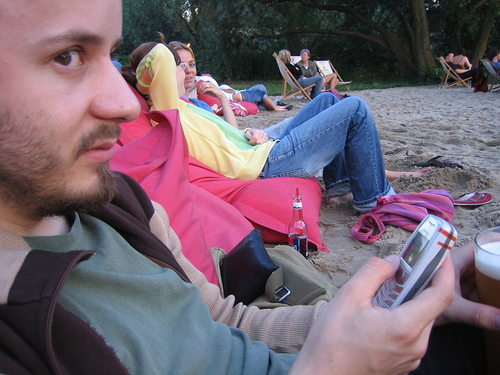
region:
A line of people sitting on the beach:
[8, 0, 281, 373]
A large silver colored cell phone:
[357, 213, 464, 315]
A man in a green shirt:
[6, 2, 288, 374]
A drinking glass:
[471, 217, 499, 309]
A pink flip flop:
[436, 183, 498, 212]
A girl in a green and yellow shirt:
[136, 39, 268, 171]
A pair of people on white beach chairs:
[267, 46, 332, 106]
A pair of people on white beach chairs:
[432, 42, 472, 91]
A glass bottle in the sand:
[277, 185, 327, 255]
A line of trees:
[124, 2, 499, 78]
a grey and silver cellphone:
[368, 210, 460, 312]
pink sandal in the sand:
[453, 189, 495, 209]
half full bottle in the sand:
[286, 187, 309, 258]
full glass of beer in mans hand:
[473, 223, 499, 364]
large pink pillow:
[118, 82, 324, 248]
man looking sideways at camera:
[1, 0, 144, 212]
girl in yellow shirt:
[131, 38, 279, 176]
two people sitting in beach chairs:
[268, 45, 354, 104]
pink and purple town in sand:
[351, 187, 454, 245]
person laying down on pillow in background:
[219, 84, 291, 114]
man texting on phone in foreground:
[10, 7, 493, 357]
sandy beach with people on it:
[305, 74, 497, 212]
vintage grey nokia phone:
[350, 203, 451, 321]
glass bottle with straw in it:
[263, 177, 330, 255]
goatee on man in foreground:
[65, 125, 135, 218]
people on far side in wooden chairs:
[265, 59, 347, 105]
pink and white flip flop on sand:
[444, 183, 498, 203]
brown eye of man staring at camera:
[45, 38, 83, 73]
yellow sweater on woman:
[145, 48, 289, 192]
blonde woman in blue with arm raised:
[168, 42, 241, 120]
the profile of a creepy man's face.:
[0, 0, 141, 232]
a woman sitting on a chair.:
[133, 20, 469, 265]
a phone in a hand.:
[353, 206, 477, 334]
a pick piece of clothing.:
[118, 105, 342, 283]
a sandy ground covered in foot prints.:
[262, 89, 497, 292]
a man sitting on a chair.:
[266, 46, 353, 118]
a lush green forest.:
[95, 1, 496, 84]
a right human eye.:
[31, 34, 109, 81]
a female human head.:
[122, 36, 194, 126]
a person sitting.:
[155, 39, 205, 104]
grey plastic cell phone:
[365, 206, 457, 316]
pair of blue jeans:
[262, 90, 392, 202]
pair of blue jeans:
[293, 73, 328, 98]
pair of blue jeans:
[237, 81, 275, 106]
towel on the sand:
[345, 181, 454, 251]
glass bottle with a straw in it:
[281, 183, 310, 261]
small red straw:
[291, 181, 297, 202]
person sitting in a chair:
[272, 48, 327, 103]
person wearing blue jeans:
[123, 38, 404, 217]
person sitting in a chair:
[433, 46, 477, 87]